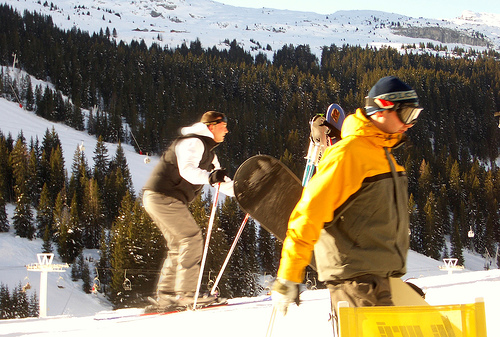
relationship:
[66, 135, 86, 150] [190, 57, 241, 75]
snow on trees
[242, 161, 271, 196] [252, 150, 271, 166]
ski board has edge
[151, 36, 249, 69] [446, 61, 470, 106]
valley has trees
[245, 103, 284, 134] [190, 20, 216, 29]
forest amidst snow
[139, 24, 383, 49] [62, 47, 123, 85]
mountain has forest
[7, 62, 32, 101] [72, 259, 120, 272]
ski lift has support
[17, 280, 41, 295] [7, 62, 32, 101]
buggy of ski lift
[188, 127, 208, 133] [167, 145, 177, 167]
sweatshirt under vest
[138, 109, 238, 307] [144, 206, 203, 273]
man wearing pants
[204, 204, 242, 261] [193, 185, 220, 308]
set pf ski pole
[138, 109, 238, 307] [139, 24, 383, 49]
man on mountain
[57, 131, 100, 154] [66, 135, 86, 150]
slope has snow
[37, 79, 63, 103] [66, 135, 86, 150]
hill has snow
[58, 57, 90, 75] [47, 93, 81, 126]
trees in rows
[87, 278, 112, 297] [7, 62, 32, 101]
carts have ski lift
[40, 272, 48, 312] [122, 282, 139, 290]
pole on lift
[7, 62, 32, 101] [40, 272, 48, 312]
ski lift has pole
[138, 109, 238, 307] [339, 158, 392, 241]
man wearing jacket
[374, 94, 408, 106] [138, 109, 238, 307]
hat on man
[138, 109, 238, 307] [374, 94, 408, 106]
man wearing hat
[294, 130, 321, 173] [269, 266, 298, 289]
skies are being held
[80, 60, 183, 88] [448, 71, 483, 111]
background has forest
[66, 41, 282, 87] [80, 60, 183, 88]
forrest in background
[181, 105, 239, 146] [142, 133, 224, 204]
man wearing black vest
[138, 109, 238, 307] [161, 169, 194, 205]
man has black vest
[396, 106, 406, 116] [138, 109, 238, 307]
googles on man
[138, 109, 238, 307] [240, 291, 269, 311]
man on slope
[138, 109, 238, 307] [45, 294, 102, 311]
man on ski slope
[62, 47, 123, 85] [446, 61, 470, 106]
forest with trees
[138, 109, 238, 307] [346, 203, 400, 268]
man wearing jacket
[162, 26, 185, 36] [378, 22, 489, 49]
snow capped on top of mountains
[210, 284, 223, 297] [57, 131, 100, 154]
chair on slope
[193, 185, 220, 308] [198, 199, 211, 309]
ski pole left ski pole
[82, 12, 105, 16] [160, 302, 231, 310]
snow has ski